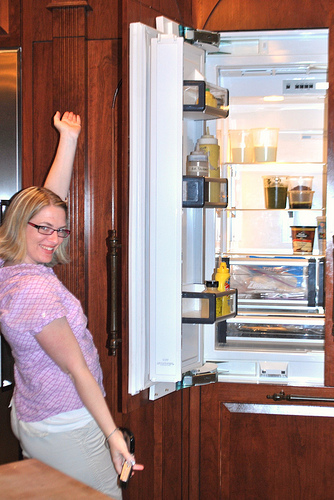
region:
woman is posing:
[0, 110, 143, 498]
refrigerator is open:
[118, 2, 329, 414]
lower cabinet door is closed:
[199, 380, 333, 498]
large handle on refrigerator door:
[107, 229, 122, 354]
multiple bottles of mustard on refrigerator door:
[196, 124, 231, 318]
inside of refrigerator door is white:
[128, 14, 205, 399]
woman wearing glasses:
[26, 220, 71, 238]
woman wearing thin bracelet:
[104, 425, 118, 443]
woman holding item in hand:
[119, 452, 134, 481]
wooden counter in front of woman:
[0, 456, 114, 498]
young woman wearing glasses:
[0, 163, 103, 497]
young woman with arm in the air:
[3, 86, 125, 488]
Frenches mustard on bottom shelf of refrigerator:
[218, 259, 230, 313]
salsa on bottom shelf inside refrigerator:
[276, 220, 318, 259]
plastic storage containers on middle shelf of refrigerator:
[245, 171, 329, 214]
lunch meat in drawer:
[226, 255, 321, 353]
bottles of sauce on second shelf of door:
[192, 123, 224, 203]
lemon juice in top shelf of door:
[186, 81, 228, 116]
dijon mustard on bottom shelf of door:
[196, 277, 224, 322]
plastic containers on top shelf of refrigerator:
[220, 118, 300, 165]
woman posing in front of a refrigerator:
[0, 107, 140, 496]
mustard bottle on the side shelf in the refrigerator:
[214, 259, 233, 313]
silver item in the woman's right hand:
[119, 456, 134, 485]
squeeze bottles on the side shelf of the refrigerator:
[187, 126, 222, 202]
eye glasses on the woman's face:
[26, 222, 70, 238]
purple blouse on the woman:
[2, 264, 104, 416]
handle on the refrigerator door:
[103, 226, 118, 356]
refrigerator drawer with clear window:
[222, 253, 323, 305]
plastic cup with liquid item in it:
[264, 175, 289, 212]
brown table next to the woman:
[4, 458, 123, 499]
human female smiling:
[1, 185, 93, 279]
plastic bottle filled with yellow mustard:
[208, 259, 242, 321]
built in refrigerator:
[120, 8, 332, 422]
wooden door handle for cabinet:
[95, 211, 120, 360]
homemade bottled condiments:
[186, 123, 227, 210]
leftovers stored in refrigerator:
[222, 122, 284, 165]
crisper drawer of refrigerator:
[206, 244, 323, 311]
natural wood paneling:
[22, 8, 107, 444]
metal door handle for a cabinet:
[264, 385, 330, 412]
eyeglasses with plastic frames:
[20, 212, 83, 250]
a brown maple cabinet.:
[174, 394, 333, 498]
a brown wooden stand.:
[0, 456, 120, 498]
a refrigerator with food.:
[172, 207, 333, 387]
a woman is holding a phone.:
[112, 454, 142, 493]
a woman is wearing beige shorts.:
[44, 419, 97, 466]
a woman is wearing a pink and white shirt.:
[14, 311, 50, 404]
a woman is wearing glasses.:
[18, 214, 79, 240]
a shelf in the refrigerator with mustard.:
[177, 115, 237, 214]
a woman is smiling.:
[0, 186, 87, 274]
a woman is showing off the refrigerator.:
[0, 61, 333, 498]